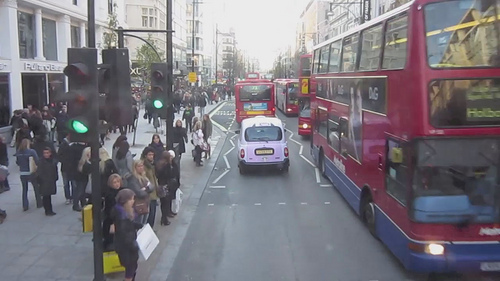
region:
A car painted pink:
[237, 112, 292, 177]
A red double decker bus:
[308, 0, 498, 272]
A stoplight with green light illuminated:
[62, 40, 101, 142]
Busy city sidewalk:
[2, 45, 224, 275]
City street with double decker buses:
[188, 0, 468, 270]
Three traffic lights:
[48, 6, 195, 135]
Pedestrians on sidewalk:
[7, 40, 226, 279]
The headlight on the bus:
[396, 215, 483, 271]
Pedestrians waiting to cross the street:
[86, 130, 193, 275]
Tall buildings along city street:
[0, 0, 237, 94]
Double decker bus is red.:
[301, 0, 499, 278]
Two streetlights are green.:
[53, 48, 190, 148]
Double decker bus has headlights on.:
[301, 2, 498, 273]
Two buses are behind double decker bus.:
[273, 69, 321, 144]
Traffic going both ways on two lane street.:
[164, 52, 499, 279]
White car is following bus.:
[210, 68, 300, 177]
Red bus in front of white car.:
[211, 60, 283, 136]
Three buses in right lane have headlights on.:
[281, 7, 499, 277]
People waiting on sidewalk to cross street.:
[91, 135, 221, 280]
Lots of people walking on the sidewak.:
[1, 64, 236, 279]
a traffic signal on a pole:
[58, 37, 110, 195]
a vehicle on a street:
[231, 110, 299, 227]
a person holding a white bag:
[110, 187, 167, 275]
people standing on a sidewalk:
[12, 134, 82, 236]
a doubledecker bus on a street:
[306, 5, 496, 277]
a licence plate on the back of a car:
[252, 144, 279, 169]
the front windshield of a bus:
[397, 128, 499, 243]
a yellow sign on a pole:
[183, 57, 200, 96]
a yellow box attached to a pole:
[73, 193, 108, 244]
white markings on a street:
[211, 103, 241, 198]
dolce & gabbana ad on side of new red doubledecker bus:
[312, 72, 385, 167]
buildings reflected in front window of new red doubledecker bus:
[418, 2, 498, 123]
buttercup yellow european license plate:
[251, 147, 276, 156]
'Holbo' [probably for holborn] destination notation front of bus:
[463, 103, 498, 118]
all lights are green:
[60, 45, 170, 147]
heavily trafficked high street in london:
[156, 0, 463, 280]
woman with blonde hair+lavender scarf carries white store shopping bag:
[101, 183, 165, 279]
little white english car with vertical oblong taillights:
[232, 110, 296, 181]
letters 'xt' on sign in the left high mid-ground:
[127, 62, 144, 76]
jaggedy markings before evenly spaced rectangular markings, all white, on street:
[198, 125, 340, 217]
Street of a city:
[1, 5, 495, 279]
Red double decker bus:
[300, 2, 495, 272]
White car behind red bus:
[230, 114, 298, 179]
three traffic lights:
[42, 4, 193, 279]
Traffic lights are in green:
[45, 4, 193, 272]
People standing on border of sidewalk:
[91, 101, 226, 276]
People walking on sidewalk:
[4, 81, 104, 203]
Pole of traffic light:
[81, 7, 112, 277]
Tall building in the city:
[120, 4, 262, 86]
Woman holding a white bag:
[108, 192, 176, 279]